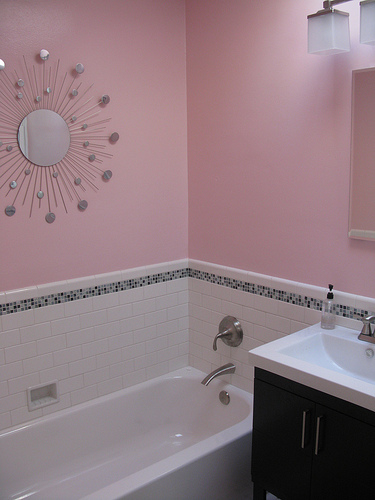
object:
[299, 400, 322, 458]
handles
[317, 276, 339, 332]
bottle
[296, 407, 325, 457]
handles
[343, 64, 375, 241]
mirror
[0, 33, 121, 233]
wall decoration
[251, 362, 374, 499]
cabinet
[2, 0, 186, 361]
wall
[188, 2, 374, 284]
wall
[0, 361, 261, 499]
bathtub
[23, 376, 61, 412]
soapdish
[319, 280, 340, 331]
soap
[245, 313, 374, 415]
sink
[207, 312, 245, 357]
handle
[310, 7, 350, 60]
light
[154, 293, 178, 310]
tile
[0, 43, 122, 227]
design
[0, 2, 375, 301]
wall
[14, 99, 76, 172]
mirror